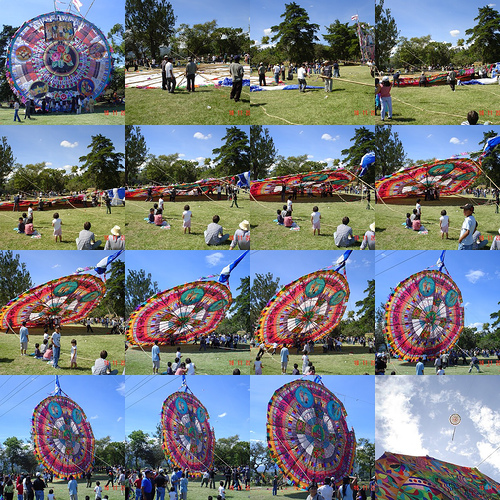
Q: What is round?
A: A kite.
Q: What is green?
A: Grass.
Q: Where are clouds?
A: In the sky.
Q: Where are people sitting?
A: On the grass.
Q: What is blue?
A: Sky.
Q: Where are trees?
A: In the distance.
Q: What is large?
A: The kite.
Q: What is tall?
A: Trees.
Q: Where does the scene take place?
A: On a grassy field.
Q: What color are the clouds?
A: White.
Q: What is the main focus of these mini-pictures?
A: A large kite.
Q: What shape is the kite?
A: Round.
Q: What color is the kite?
A: Multi-colored.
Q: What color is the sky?
A: Blue.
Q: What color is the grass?
A: Green.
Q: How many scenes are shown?
A: 16.